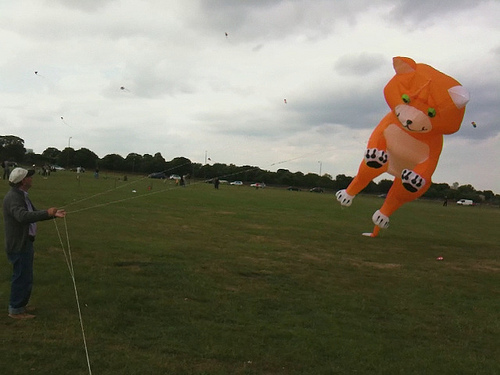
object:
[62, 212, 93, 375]
string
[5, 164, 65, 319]
man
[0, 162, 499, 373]
grass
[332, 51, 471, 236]
balloon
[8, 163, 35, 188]
hat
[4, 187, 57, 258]
jacket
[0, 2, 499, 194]
sky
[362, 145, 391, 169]
paws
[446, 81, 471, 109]
his ear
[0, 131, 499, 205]
trees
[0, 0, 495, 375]
background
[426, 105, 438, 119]
eyes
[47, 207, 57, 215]
hands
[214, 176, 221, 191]
people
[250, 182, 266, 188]
cars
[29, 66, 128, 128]
three kites